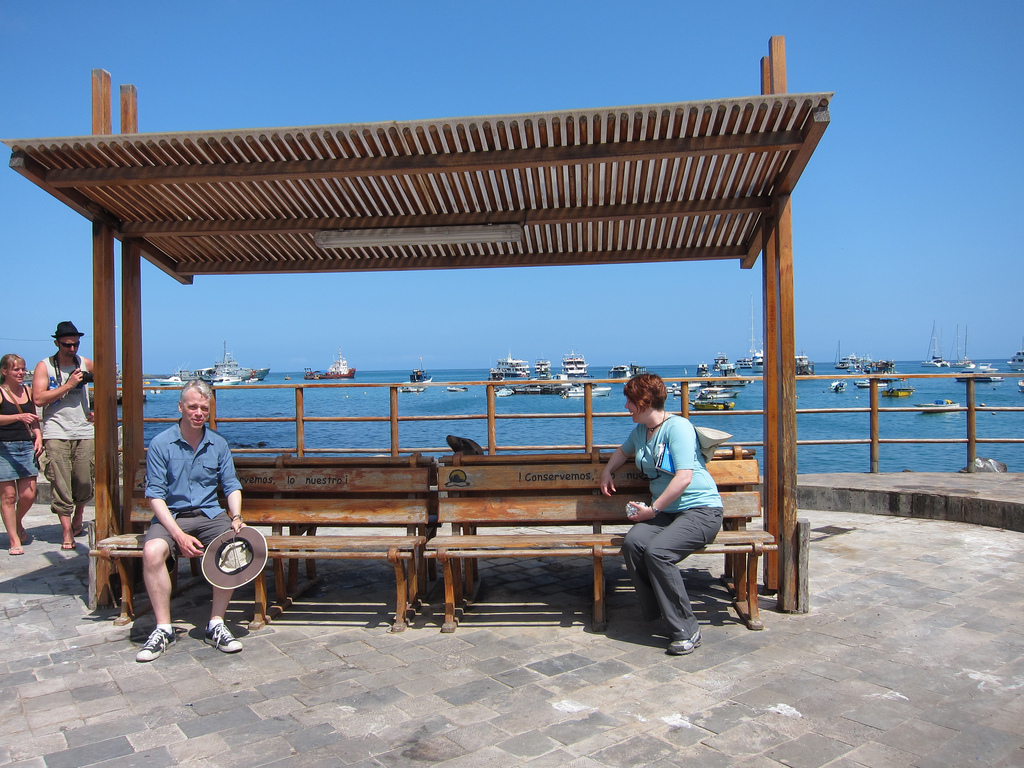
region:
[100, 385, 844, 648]
Two people sitting on benches.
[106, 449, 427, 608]
A wooden bench.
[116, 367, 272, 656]
A man sitting on a bench.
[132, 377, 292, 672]
A man with grey hair.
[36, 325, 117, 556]
A guy wearing a hat.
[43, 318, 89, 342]
A round black hat.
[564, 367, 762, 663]
A woman sitting on a bench.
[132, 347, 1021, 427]
Boats in the water.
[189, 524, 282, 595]
A round brown hat.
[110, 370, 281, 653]
A man holding a hat.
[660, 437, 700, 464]
the shirt is blue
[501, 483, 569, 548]
the bench is weathered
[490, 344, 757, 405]
the boats are in the water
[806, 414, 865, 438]
the water is very blue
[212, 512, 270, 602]
he is holding a hat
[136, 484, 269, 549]
the man is sitting on the bench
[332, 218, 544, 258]
the light is off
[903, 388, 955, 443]
a boat on the a water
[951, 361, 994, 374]
a boat on the a water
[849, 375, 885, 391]
a boat on the a water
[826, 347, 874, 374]
a boat on the a water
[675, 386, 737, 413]
a boat on the a water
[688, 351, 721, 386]
a boat on the a water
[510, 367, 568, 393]
a boat on the a water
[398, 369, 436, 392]
a boat on the a water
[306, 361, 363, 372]
a boat on the a water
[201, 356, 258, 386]
a boat on the a water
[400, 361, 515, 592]
A person eating a orange.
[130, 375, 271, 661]
A person sitting down.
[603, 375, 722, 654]
A person is sitting down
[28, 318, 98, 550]
A person walking on a sidewalk.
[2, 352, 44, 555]
A person walking on a sidewalk.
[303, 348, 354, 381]
A boat on the water.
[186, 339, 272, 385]
A boat on the water.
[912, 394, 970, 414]
A boat on the water.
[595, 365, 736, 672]
woman sitting on bench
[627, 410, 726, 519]
woman wearing blue shirt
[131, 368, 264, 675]
man sitting on end of bench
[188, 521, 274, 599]
man holding sun hat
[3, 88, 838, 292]
wooden awning over benches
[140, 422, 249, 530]
man wearing blue shirt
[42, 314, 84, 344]
man wearing a hat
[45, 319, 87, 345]
man's hat is black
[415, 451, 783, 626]
right bench under awning is wooden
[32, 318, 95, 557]
man wearing black hat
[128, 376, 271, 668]
an holding hat in hand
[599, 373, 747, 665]
woman sittting on bench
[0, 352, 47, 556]
woman standing next to man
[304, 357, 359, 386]
boat in water behind man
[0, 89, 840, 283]
wooden canopy on bench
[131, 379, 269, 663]
man wearing gray shorts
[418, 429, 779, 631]
wooden bench next to wooden bench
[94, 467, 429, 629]
wooden bench next to wooden bench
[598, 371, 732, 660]
a woman sitting on a bench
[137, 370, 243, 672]
a man sitting on a bench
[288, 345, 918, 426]
several boats in the water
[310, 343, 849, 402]
a large body of water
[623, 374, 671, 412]
a woman with short hair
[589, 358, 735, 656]
woman sitting on a bench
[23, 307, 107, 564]
man wearing a black hat